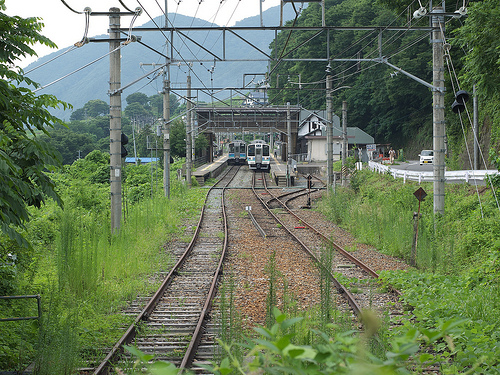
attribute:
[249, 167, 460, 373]
train track — old, rusty, brown, metal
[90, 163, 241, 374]
train track — old, rusty, brown, metal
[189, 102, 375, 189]
train station — rural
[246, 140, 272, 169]
train — white, travelling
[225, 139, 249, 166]
train — blue, travelling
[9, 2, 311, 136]
mountains — large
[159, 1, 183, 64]
wire — suspended, electrical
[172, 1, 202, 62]
wire — suspended, electrical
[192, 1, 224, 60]
wire — suspended, electrical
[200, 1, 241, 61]
wire — suspended, electrical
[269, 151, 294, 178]
platform — concrete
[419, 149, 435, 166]
car — white, sedan, travelling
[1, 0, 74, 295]
tree — tall, green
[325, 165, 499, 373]
weeds — overgrown, green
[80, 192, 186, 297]
grass — overgrown, tall, green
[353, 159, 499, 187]
guardrail — white, metal, painted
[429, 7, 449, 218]
pole — wooden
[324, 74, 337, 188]
pole — wooden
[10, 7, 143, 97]
wire — suspended, electrical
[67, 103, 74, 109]
leaf — green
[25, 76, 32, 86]
leaf — green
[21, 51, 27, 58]
leaf — green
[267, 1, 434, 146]
trees — huge, green